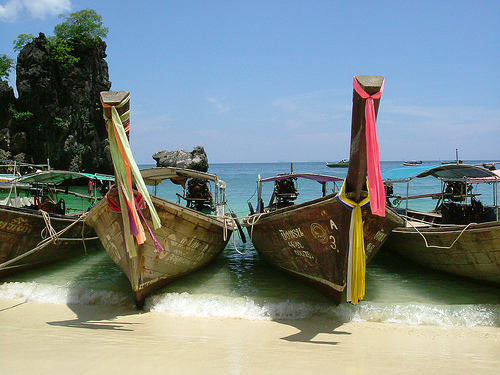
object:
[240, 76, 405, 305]
boat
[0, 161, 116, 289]
boat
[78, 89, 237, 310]
boat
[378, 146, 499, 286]
boat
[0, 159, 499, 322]
waves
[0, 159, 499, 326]
sea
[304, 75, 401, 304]
front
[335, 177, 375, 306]
ribbons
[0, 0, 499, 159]
sky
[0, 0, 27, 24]
clouds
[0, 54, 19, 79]
trees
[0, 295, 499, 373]
sand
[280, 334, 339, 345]
edge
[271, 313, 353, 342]
shade